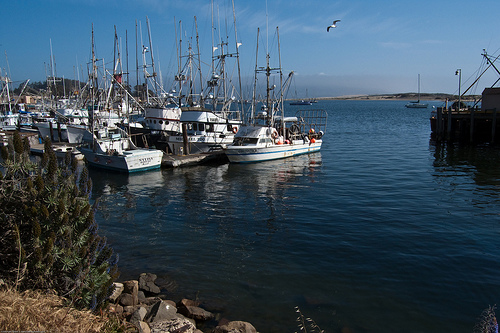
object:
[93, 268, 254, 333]
pile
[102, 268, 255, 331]
rocks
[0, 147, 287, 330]
shore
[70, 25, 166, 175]
boat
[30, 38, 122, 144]
boat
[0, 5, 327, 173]
parked boats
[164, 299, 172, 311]
line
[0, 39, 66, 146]
boats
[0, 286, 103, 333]
grass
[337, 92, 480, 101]
land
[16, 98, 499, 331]
water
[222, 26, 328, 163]
boat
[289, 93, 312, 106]
boat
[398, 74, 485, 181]
shore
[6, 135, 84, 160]
train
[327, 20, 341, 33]
bird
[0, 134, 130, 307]
bushes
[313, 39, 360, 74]
clouds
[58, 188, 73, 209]
flowers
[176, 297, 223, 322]
gray rock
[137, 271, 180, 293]
gray rock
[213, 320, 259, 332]
gray rock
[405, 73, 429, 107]
boats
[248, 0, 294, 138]
mast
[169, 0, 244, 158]
boat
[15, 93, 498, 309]
harbor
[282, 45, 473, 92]
sky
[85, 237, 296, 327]
shore line